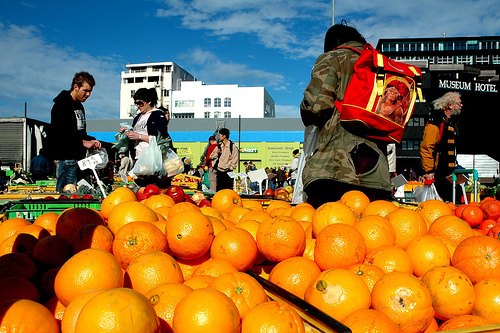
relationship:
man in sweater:
[45, 71, 110, 194] [47, 89, 97, 160]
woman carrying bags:
[123, 86, 191, 188] [134, 136, 184, 180]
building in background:
[119, 52, 279, 121] [4, 5, 495, 214]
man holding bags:
[421, 90, 472, 202] [413, 178, 444, 203]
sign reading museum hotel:
[434, 72, 500, 96] [436, 78, 498, 92]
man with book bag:
[294, 18, 427, 200] [336, 43, 423, 145]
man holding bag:
[45, 71, 110, 194] [83, 146, 111, 169]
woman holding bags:
[117, 88, 178, 188] [134, 136, 184, 180]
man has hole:
[294, 18, 427, 200] [348, 141, 381, 177]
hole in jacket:
[348, 141, 381, 177] [299, 41, 408, 195]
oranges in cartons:
[9, 171, 495, 324] [9, 198, 101, 218]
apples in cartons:
[134, 181, 214, 207] [9, 198, 101, 218]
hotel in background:
[394, 61, 499, 182] [4, 5, 495, 214]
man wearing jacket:
[211, 125, 242, 192] [218, 139, 243, 174]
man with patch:
[294, 18, 427, 200] [346, 145, 384, 174]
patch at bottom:
[346, 145, 384, 174] [304, 150, 393, 188]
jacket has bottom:
[299, 41, 408, 195] [304, 150, 393, 188]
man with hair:
[421, 90, 472, 202] [433, 95, 460, 111]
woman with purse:
[123, 86, 191, 188] [153, 133, 172, 158]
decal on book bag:
[374, 81, 415, 122] [336, 43, 423, 145]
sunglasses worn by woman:
[131, 97, 147, 107] [123, 86, 191, 188]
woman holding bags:
[123, 86, 191, 188] [134, 136, 184, 180]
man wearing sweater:
[45, 71, 110, 194] [47, 89, 96, 164]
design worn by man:
[76, 106, 90, 132] [45, 71, 110, 194]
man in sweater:
[45, 71, 110, 194] [47, 89, 96, 164]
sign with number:
[76, 150, 115, 203] [80, 162, 87, 170]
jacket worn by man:
[299, 41, 408, 195] [294, 18, 427, 200]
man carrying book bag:
[294, 18, 427, 200] [336, 43, 423, 145]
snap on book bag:
[376, 69, 386, 79] [336, 43, 423, 145]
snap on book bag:
[414, 74, 425, 85] [336, 43, 423, 145]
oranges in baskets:
[9, 171, 495, 324] [245, 265, 351, 331]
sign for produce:
[76, 150, 115, 203] [5, 171, 500, 327]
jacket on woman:
[299, 41, 408, 195] [299, 16, 427, 203]